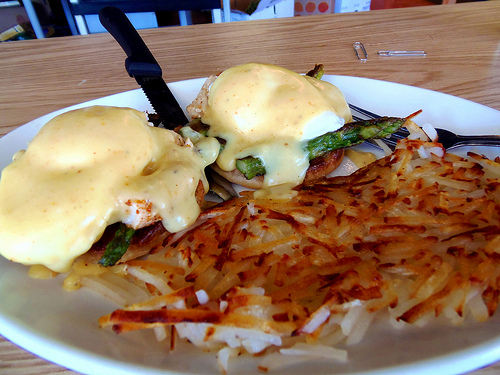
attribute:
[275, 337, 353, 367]
hash brown — white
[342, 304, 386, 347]
hash brown — white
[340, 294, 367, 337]
hash brown — white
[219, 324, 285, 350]
hash brown — white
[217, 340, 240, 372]
hash brown — white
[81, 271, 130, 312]
hash brown — white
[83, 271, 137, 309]
hash brown — white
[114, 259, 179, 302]
hash brown — white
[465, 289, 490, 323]
hash brown — white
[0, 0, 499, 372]
table — wooden , Round 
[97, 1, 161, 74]
handle — black 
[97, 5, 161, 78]
handle — black 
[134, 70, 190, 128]
blade — serrated 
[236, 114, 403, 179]
asperagus — green 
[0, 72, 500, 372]
plate — white , ceramic 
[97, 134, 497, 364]
hashbrowns — golden brown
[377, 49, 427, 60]
paperclip — metal 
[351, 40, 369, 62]
paperclip — metal 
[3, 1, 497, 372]
tabletop — light brown, wooden 